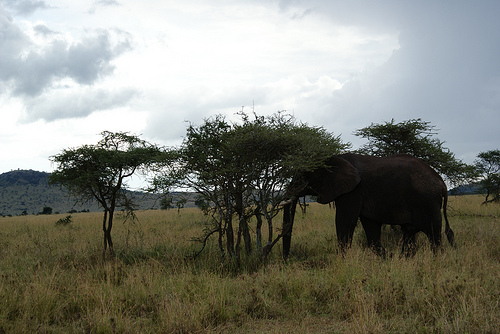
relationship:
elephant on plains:
[328, 171, 445, 220] [38, 139, 267, 333]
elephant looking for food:
[328, 171, 445, 220] [279, 260, 284, 265]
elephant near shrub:
[328, 171, 445, 220] [160, 195, 172, 212]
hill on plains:
[14, 173, 56, 200] [38, 139, 267, 333]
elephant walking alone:
[328, 171, 445, 220] [399, 209, 414, 227]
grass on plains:
[0, 193, 499, 333] [38, 139, 267, 333]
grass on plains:
[141, 236, 169, 258] [38, 139, 267, 333]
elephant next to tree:
[328, 171, 445, 220] [207, 132, 246, 257]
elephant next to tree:
[328, 171, 445, 220] [58, 137, 158, 272]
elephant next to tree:
[328, 171, 445, 220] [193, 126, 255, 263]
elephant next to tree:
[328, 171, 445, 220] [381, 126, 436, 157]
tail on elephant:
[447, 202, 448, 224] [328, 171, 445, 220]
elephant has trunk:
[328, 171, 445, 220] [287, 207, 291, 251]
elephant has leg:
[328, 171, 445, 220] [336, 214, 351, 245]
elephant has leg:
[328, 171, 445, 220] [367, 224, 377, 248]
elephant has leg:
[328, 171, 445, 220] [408, 233, 414, 252]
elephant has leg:
[328, 171, 445, 220] [432, 232, 442, 247]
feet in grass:
[333, 244, 445, 259] [0, 195, 497, 332]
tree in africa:
[161, 105, 342, 263] [0, 0, 497, 331]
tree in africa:
[52, 130, 174, 259] [0, 0, 497, 331]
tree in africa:
[352, 117, 477, 173] [0, 0, 497, 331]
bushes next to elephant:
[43, 100, 483, 265] [277, 145, 464, 265]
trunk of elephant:
[258, 185, 315, 272] [216, 124, 457, 282]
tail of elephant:
[442, 192, 456, 244] [254, 141, 478, 245]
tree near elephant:
[161, 105, 342, 263] [273, 154, 457, 264]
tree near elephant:
[52, 130, 174, 259] [273, 154, 457, 264]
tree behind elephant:
[52, 130, 174, 259] [271, 144, 491, 261]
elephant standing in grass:
[273, 154, 457, 264] [321, 246, 450, 268]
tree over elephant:
[52, 130, 174, 259] [273, 154, 457, 264]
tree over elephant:
[161, 105, 342, 263] [273, 154, 457, 264]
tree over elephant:
[352, 117, 477, 173] [273, 154, 457, 264]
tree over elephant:
[476, 146, 498, 204] [273, 154, 457, 264]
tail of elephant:
[442, 192, 456, 244] [444, 189, 459, 249]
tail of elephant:
[442, 192, 456, 244] [273, 154, 457, 264]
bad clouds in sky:
[0, 3, 401, 195] [2, 0, 499, 192]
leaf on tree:
[139, 139, 146, 144] [55, 130, 186, 254]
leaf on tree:
[130, 216, 137, 221] [55, 130, 186, 254]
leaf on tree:
[74, 189, 79, 196] [55, 130, 186, 254]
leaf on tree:
[100, 143, 103, 149] [55, 130, 186, 254]